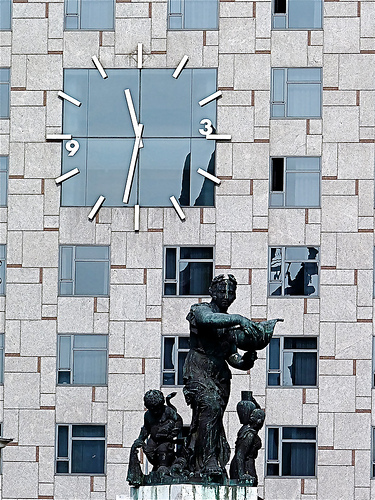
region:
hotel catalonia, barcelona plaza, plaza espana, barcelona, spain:
[332, 440, 374, 451]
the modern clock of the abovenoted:
[41, 37, 239, 238]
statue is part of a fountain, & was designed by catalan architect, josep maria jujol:
[89, 256, 297, 499]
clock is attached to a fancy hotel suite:
[37, 36, 244, 229]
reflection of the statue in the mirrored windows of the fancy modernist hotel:
[262, 239, 330, 307]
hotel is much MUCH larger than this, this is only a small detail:
[1, 0, 374, 499]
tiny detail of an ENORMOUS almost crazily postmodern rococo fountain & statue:
[105, 264, 297, 499]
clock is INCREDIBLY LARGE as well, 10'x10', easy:
[30, 30, 246, 234]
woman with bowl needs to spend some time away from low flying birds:
[176, 259, 290, 484]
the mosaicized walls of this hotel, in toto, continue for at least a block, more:
[2, 0, 373, 498]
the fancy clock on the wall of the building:
[42, 42, 227, 226]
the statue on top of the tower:
[125, 270, 268, 485]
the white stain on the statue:
[221, 271, 230, 299]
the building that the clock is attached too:
[2, 1, 370, 494]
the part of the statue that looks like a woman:
[185, 271, 250, 481]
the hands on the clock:
[114, 86, 145, 201]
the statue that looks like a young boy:
[136, 388, 182, 475]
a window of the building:
[55, 421, 109, 471]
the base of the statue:
[131, 484, 264, 497]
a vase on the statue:
[234, 391, 253, 423]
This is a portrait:
[227, 387, 293, 498]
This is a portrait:
[132, 366, 188, 481]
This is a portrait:
[178, 257, 263, 469]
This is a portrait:
[227, 386, 278, 497]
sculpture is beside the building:
[122, 237, 294, 480]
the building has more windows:
[38, 167, 140, 397]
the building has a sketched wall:
[57, 51, 231, 207]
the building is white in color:
[13, 296, 93, 435]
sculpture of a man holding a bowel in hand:
[185, 269, 241, 457]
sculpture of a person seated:
[130, 380, 182, 478]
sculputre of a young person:
[235, 396, 275, 496]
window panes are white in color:
[53, 429, 118, 494]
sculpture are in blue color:
[193, 289, 285, 472]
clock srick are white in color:
[53, 83, 249, 222]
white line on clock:
[136, 42, 145, 69]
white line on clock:
[171, 54, 190, 77]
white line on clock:
[198, 89, 223, 106]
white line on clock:
[204, 133, 232, 141]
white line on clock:
[195, 165, 221, 184]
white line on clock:
[169, 194, 185, 221]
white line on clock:
[134, 204, 140, 232]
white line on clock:
[87, 194, 105, 221]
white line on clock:
[54, 168, 80, 186]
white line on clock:
[45, 131, 72, 141]